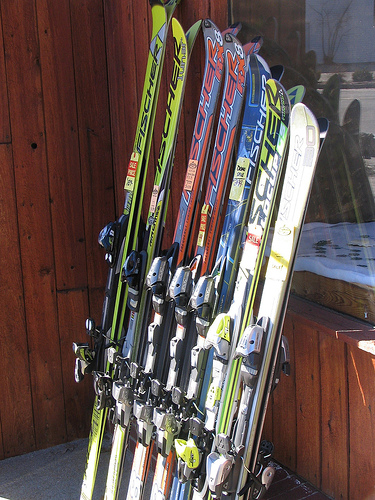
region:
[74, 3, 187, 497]
a set of green skis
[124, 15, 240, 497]
a set of red blue skis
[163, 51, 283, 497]
a set of blue skis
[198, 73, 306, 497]
aa set of green yellow skis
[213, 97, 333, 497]
a set of white skis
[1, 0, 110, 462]
a brown wood paneled wall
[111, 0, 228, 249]
a brown wood paneled wall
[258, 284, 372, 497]
a brown wood paneled wall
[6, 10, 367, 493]
Exterior view, winter sunlight.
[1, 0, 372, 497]
Shot, showing store facade, with window and merchandise display.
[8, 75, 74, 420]
Dark, rich, wood paneling.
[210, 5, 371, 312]
Recessed store window, topping wood paneling.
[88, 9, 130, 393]
Corner, between store facades.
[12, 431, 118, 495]
White dusting, covering walk area, between store fronts.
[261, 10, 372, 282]
Outside trees, buildings and merchandise reflected in store window.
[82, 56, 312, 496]
Neatly displayed skis, leaning against store front.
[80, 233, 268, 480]
Boot bindings, almost exactly lined up.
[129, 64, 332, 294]
Colorful, brand logos, decorating skis.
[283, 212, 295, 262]
ski is white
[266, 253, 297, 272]
yellow stripe on ski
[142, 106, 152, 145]
bright yellow color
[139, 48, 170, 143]
FISCHER written on the ski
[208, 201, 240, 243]
ski is blue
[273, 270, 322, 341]
skis are in front of the window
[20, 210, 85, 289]
building is made of wood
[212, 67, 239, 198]
FISCHER is written in red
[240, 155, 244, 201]
tag on the skis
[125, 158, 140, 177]
SALE PRICE written on tag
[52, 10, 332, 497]
seven sets of skis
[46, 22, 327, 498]
skis leaning up against the side of a bulding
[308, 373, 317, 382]
small brown spot on the wood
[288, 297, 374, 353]
wooden ledge under the window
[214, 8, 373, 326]
window on the side of the building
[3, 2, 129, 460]
wood paneling on the wall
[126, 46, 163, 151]
black writing on the ski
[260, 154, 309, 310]
light shining on the ski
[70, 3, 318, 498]
tall and thin skis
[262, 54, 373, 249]
reflection in the window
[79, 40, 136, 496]
pair of yellow skis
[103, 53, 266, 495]
pairs of red skis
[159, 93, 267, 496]
pair of blue skis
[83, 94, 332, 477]
numerous skis standing in pairs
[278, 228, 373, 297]
white counter behind skis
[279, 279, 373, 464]
cherry red wood behind skis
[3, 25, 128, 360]
brown wall left of skis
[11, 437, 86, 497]
skis on grey carpet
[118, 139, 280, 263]
yellow and red tags on skis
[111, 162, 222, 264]
red stripes on tags